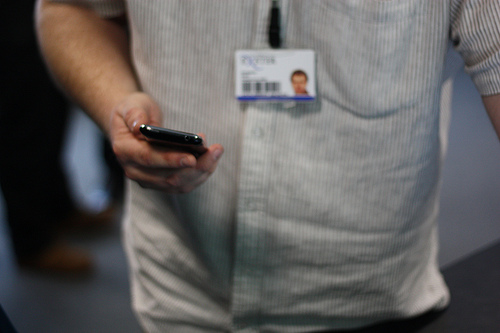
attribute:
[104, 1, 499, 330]
shirt — striped, uniform, white, blue, grey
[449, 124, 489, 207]
wall — white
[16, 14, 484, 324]
man — light skinned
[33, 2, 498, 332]
man — standing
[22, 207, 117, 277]
shoes — brown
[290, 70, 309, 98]
face — man's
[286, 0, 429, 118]
pocket — saggy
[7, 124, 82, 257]
trouser — black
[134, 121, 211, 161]
phone — black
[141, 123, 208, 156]
phone — mobile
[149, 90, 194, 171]
phone — mobile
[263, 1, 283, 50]
lanyard — black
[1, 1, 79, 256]
slacks — dark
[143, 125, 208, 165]
phone — mobile, black